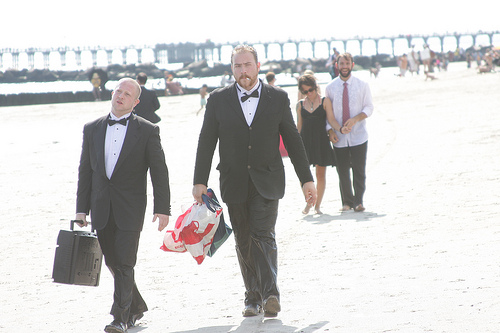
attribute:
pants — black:
[93, 200, 150, 324]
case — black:
[49, 218, 102, 285]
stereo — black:
[47, 217, 106, 287]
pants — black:
[95, 196, 142, 318]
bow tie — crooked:
[241, 88, 263, 105]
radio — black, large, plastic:
[14, 209, 129, 287]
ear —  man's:
[133, 99, 156, 103]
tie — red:
[335, 81, 352, 136]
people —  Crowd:
[399, 52, 499, 86]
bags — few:
[159, 186, 233, 266]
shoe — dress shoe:
[246, 283, 302, 313]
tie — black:
[233, 84, 263, 104]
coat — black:
[188, 75, 309, 293]